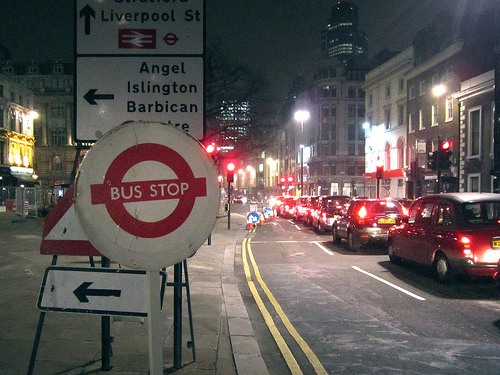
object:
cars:
[388, 192, 500, 284]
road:
[0, 201, 500, 373]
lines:
[234, 237, 307, 375]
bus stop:
[110, 181, 190, 201]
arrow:
[72, 282, 126, 303]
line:
[348, 264, 425, 300]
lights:
[361, 121, 371, 130]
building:
[359, 12, 500, 214]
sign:
[73, 122, 221, 269]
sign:
[35, 268, 167, 315]